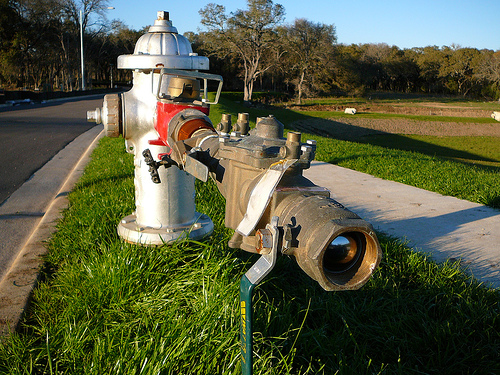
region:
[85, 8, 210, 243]
Silver fire extinguisher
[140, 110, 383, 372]
Large metal hose attachment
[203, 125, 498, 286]
Paved white sidewalk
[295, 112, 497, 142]
Area of dirt in the grass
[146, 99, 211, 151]
Red tape on a fire extinguisher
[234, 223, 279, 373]
Green metal handle on a hose attachment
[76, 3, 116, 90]
Tall metal street lamp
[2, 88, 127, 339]
Single lane road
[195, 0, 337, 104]
Two trees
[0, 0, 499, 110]
Large forest of trees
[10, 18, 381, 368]
silver, red and gold fire hydrant near curb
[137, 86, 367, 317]
label on metal extension on red hydrant valve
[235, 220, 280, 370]
yellow and green lever attached by bolt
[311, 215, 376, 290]
round opening with reflective lens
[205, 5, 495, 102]
two trees in front of rows of trees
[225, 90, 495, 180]
long and pointy shadow on ground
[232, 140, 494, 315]
gray paved path between grass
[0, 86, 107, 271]
black paving over grey street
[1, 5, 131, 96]
lamp pole and trees on other side of street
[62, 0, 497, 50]
clear blue skies over trees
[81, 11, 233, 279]
this is a fire hydrant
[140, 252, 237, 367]
this is grass on the ground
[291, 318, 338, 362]
this is grass on the ground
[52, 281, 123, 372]
this is grass on the ground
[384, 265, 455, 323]
this is grass on the ground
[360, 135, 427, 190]
this is grass on the ground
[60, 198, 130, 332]
this is grass on the ground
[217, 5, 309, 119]
this is a tree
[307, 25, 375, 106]
his is a tree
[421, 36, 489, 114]
his is a tree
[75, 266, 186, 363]
Grass is green color.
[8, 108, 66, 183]
Road is grey color.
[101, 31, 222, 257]
Hydrant is silve color.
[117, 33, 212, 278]
Hydrant is in middle of grass.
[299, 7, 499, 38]
Sky is blue color.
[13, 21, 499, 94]
Trees are green color.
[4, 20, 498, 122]
Trees are behind the hydrant.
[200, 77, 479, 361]
Shadow is in the ground.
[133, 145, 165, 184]
Valve is black color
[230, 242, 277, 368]
Control is green color.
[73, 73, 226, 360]
This is a hydrant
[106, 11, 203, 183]
The hydrant is silver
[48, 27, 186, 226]
The hydrant is painted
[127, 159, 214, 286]
The hydrant is made of metal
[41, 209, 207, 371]
This is a patch of grass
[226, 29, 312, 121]
These are old trees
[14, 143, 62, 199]
This is stone pavement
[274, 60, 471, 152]
This is a field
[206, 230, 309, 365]
This is a metal stake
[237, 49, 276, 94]
This is an old tree